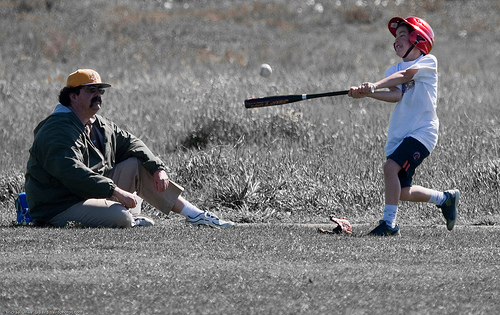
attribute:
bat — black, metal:
[240, 85, 376, 109]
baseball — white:
[259, 64, 273, 80]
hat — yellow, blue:
[61, 64, 112, 89]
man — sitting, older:
[21, 65, 242, 228]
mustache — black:
[86, 96, 104, 108]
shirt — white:
[379, 56, 439, 155]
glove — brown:
[315, 212, 355, 239]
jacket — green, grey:
[21, 100, 164, 223]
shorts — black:
[380, 137, 431, 188]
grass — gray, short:
[1, 222, 499, 314]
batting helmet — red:
[388, 15, 433, 57]